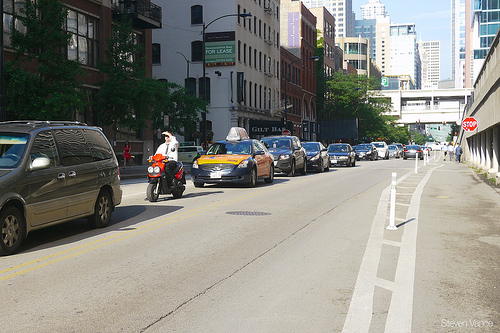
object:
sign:
[459, 115, 481, 135]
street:
[1, 136, 416, 260]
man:
[149, 130, 179, 187]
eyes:
[165, 135, 169, 138]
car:
[189, 135, 277, 187]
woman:
[123, 140, 135, 168]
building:
[444, 39, 500, 181]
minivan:
[0, 116, 123, 257]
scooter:
[145, 153, 186, 202]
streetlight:
[194, 10, 255, 140]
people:
[455, 142, 464, 163]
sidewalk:
[393, 156, 500, 332]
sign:
[202, 39, 240, 68]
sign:
[226, 123, 255, 140]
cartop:
[207, 136, 266, 155]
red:
[126, 149, 130, 158]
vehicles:
[401, 144, 425, 160]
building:
[283, 2, 319, 138]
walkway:
[370, 86, 467, 126]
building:
[166, 1, 279, 134]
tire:
[146, 181, 163, 202]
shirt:
[155, 133, 180, 160]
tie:
[165, 144, 170, 155]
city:
[1, 2, 500, 332]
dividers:
[388, 144, 428, 237]